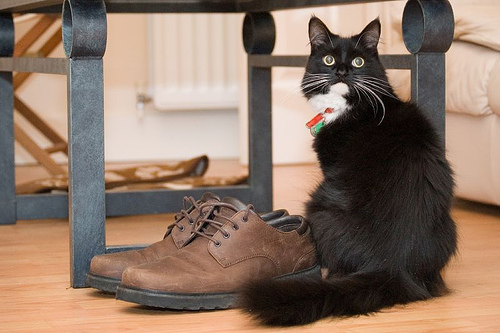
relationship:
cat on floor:
[239, 16, 459, 327] [1, 166, 498, 331]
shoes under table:
[84, 189, 319, 309] [1, 0, 454, 288]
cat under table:
[239, 16, 459, 327] [1, 0, 454, 288]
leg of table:
[60, 1, 109, 285] [1, 0, 454, 288]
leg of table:
[243, 11, 275, 209] [1, 0, 454, 288]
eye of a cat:
[321, 54, 337, 65] [239, 16, 459, 327]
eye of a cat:
[351, 56, 365, 68] [239, 16, 459, 327]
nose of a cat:
[336, 69, 347, 77] [239, 16, 459, 327]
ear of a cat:
[307, 17, 332, 44] [239, 16, 459, 327]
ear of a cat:
[359, 17, 382, 49] [239, 16, 459, 327]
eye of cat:
[321, 54, 337, 65] [239, 16, 459, 327]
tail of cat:
[241, 272, 453, 326] [239, 16, 459, 327]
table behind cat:
[1, 0, 454, 288] [239, 16, 459, 327]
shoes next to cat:
[84, 189, 319, 309] [239, 16, 459, 327]